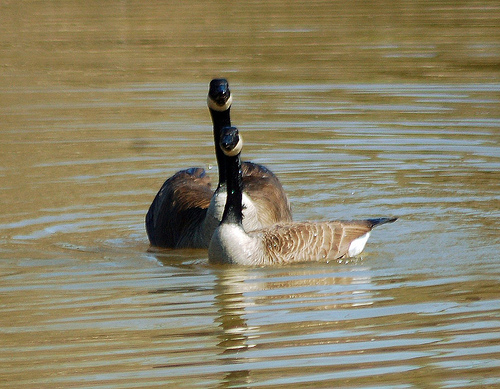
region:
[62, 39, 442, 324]
Two birds in water.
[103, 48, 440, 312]
The birds have long necks.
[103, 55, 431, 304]
The birds are feathered.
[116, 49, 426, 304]
The birds necks are lean.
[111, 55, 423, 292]
Bird in back is larger than bird in front.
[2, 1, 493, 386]
The water is calm.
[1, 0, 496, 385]
The water is ripply.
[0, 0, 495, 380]
The water is tranquil.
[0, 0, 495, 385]
The water is serene.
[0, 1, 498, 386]
The water is wavy.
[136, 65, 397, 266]
two geese in water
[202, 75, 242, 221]
black head and neck with tan band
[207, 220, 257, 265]
white feathers across chest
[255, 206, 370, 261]
brown feathers around body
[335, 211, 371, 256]
white feathers below brown feathers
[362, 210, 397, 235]
pointy black tail feathers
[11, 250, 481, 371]
long gray ridges across blue water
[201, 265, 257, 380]
long and narrow reflection on water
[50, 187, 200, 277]
circular ripples on side of body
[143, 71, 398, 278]
goose sideways in front of other goose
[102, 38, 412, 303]
two ducks in the water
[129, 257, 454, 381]
the water is rippled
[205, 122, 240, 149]
the face is black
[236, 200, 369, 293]
the duck is brown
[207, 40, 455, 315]
the water is calm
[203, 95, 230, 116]
under the chin is white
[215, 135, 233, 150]
the beak is black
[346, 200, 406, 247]
the tail is dark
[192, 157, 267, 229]
the neck is long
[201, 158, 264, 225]
the neck is black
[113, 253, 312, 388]
canadian goose is reflected in the water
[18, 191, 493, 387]
ripples go out from geese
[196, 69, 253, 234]
back neck and head with white cheeks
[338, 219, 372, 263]
white feathers under tail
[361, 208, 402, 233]
black tail feathers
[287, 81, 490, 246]
blue sky reflected in the ripples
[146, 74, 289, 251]
larger goose with darker feathers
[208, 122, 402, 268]
wing feathers with white edges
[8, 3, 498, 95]
reflection of the shore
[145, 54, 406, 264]
two geese watch the photographer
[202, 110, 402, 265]
A swan on a body of water.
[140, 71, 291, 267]
A swan near another swan.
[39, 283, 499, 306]
a ripple in water.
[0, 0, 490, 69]
a body of water near birds.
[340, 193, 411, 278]
tail feathers on a swan.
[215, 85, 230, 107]
a bill on a swan.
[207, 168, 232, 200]
A section of a swan neck.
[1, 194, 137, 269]
ripples in water.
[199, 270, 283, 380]
A reflection of a long necked swan.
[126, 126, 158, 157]
a shadow on a body of water.